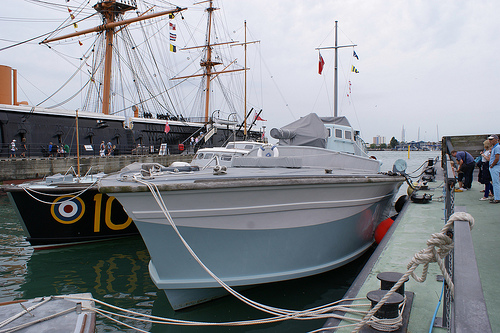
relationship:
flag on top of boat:
[307, 42, 342, 79] [99, 138, 403, 302]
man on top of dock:
[449, 146, 475, 188] [457, 181, 498, 297]